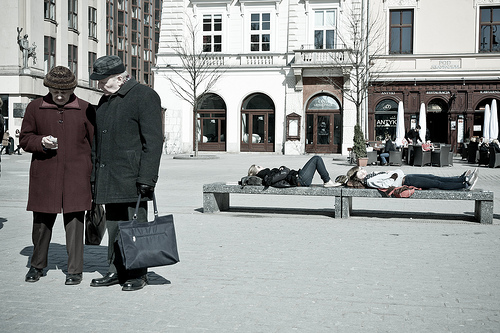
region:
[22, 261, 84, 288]
Woman wearing shoes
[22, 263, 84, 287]
Woman is wearing shoes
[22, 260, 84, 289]
Woman wearing black shoes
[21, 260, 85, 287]
Woman is wearing black shoes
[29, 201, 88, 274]
Woman wearing pants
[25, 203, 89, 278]
Woman is wearing pants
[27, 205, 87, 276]
Woman wearing brown pants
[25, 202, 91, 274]
Woman is wearing brown pants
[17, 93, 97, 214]
Woman wearing a coat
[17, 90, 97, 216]
Woman is wearing a coat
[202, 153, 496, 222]
two women laying on gray benches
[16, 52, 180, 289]
two people with hats and overcoats standing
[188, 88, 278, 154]
two arched entry doors in a white building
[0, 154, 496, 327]
large paved area of a square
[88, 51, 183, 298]
person standing with black gloves and holding a soft satchel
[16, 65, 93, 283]
person with a hat looking at something in their hand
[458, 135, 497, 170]
large potted plants at an entryway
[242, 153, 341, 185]
blond woman laying down with jeans and a black jacket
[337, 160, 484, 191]
woman with long hair laying down with a light jacket and dark pants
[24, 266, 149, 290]
leather shoes on two standing people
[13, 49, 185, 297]
two people standing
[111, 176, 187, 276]
bag in a persons hand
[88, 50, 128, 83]
hat on a persons head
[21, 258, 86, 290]
two black shoes on a persons feet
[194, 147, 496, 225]
two people lying on a bench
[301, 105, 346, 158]
door on a building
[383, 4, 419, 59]
window on a building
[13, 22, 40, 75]
sculpture on a building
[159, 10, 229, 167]
tree on the ground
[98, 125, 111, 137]
button on a persons coat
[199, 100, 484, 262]
women laying down on benches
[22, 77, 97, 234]
woman wearing red coat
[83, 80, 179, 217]
man wearing dark coat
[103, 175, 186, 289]
man holding blue bag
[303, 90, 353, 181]
brown door on building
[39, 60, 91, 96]
woman wearing brown hat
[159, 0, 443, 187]
trees without any leafs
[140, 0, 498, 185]
white building in back ground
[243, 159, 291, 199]
girl wearing black jacket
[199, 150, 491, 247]
benches made of cement